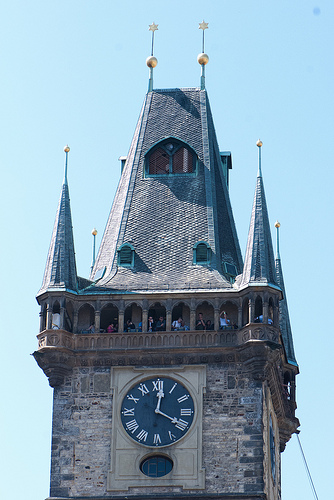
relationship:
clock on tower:
[116, 370, 200, 450] [8, 35, 318, 498]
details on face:
[133, 427, 149, 439] [128, 386, 192, 450]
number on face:
[174, 418, 187, 431] [118, 375, 196, 448]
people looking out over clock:
[82, 309, 244, 332] [116, 370, 200, 450]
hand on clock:
[155, 390, 178, 424] [113, 364, 198, 468]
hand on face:
[157, 398, 170, 423] [117, 379, 192, 443]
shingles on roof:
[31, 68, 291, 293] [152, 256, 164, 281]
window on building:
[143, 136, 198, 176] [42, 35, 292, 495]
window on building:
[143, 136, 198, 176] [54, 66, 301, 488]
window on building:
[121, 299, 144, 336] [31, 84, 300, 499]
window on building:
[148, 302, 168, 331] [31, 84, 300, 499]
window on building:
[170, 302, 191, 331] [31, 84, 300, 499]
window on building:
[194, 301, 215, 331] [31, 84, 300, 499]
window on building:
[238, 297, 250, 326] [31, 84, 300, 499]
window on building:
[253, 291, 263, 326] [31, 84, 300, 499]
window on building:
[266, 296, 275, 326] [31, 84, 300, 499]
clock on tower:
[109, 366, 204, 486] [30, 86, 300, 498]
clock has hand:
[116, 370, 200, 450] [153, 408, 180, 425]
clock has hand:
[116, 370, 200, 450] [153, 387, 165, 413]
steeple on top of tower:
[240, 174, 282, 286] [30, 86, 300, 498]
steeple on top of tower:
[274, 257, 298, 367] [30, 86, 300, 498]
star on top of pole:
[147, 20, 160, 31] [147, 31, 155, 55]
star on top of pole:
[198, 19, 208, 31] [200, 29, 206, 52]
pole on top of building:
[147, 31, 155, 55] [31, 84, 300, 499]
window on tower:
[143, 136, 198, 176] [30, 86, 300, 498]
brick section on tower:
[51, 363, 267, 499] [30, 86, 300, 498]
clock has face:
[116, 370, 200, 450] [121, 374, 193, 446]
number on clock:
[150, 379, 165, 392] [116, 370, 200, 450]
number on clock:
[169, 382, 178, 393] [114, 368, 198, 448]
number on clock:
[175, 393, 189, 403] [116, 370, 200, 450]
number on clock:
[178, 406, 193, 416] [116, 370, 200, 450]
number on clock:
[174, 418, 187, 431] [116, 370, 200, 450]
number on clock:
[166, 429, 177, 441] [116, 370, 200, 450]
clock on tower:
[116, 370, 200, 450] [35, 21, 300, 495]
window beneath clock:
[138, 453, 174, 476] [121, 375, 195, 446]